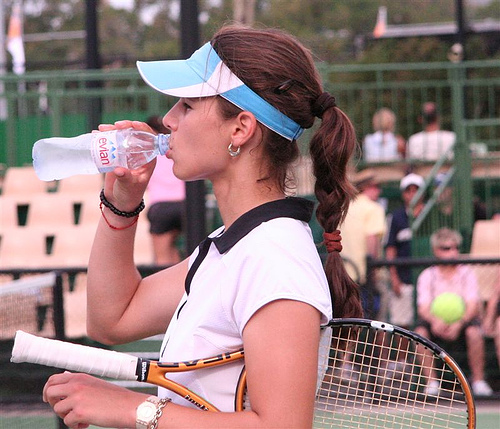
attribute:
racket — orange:
[8, 316, 475, 428]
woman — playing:
[42, 21, 365, 427]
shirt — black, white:
[154, 196, 333, 412]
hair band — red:
[312, 91, 336, 118]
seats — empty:
[1, 155, 183, 271]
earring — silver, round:
[226, 142, 242, 157]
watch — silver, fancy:
[133, 394, 159, 427]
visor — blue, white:
[136, 39, 303, 142]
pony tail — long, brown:
[310, 90, 366, 339]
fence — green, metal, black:
[1, 57, 497, 293]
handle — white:
[10, 327, 140, 384]